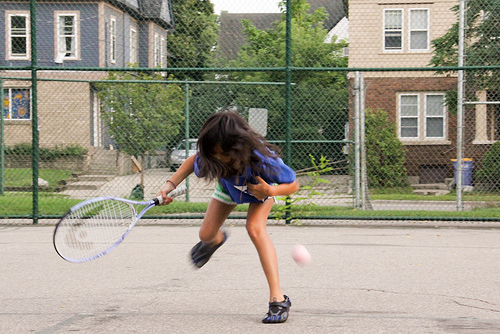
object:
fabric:
[3, 87, 33, 120]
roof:
[217, 12, 283, 58]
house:
[343, 0, 499, 194]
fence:
[0, 0, 499, 222]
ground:
[0, 217, 500, 329]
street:
[92, 168, 484, 198]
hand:
[155, 185, 176, 205]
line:
[343, 282, 499, 311]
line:
[0, 302, 408, 319]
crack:
[41, 309, 117, 332]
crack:
[126, 275, 188, 292]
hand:
[248, 176, 271, 201]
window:
[395, 91, 449, 146]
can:
[450, 158, 476, 186]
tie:
[166, 179, 176, 188]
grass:
[4, 190, 498, 218]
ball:
[289, 245, 311, 268]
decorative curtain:
[4, 88, 30, 119]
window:
[2, 88, 29, 119]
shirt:
[192, 139, 297, 205]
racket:
[52, 184, 189, 263]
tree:
[92, 66, 185, 166]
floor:
[2, 223, 496, 331]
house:
[4, 3, 179, 168]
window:
[54, 11, 79, 59]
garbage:
[447, 157, 478, 194]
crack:
[363, 282, 498, 312]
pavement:
[1, 216, 498, 328]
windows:
[385, 9, 403, 51]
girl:
[155, 111, 298, 324]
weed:
[276, 153, 348, 224]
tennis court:
[3, 224, 498, 333]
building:
[336, 0, 499, 186]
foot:
[262, 294, 292, 323]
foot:
[189, 230, 227, 268]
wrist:
[166, 172, 182, 188]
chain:
[15, 8, 480, 233]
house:
[188, 2, 348, 176]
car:
[169, 138, 199, 172]